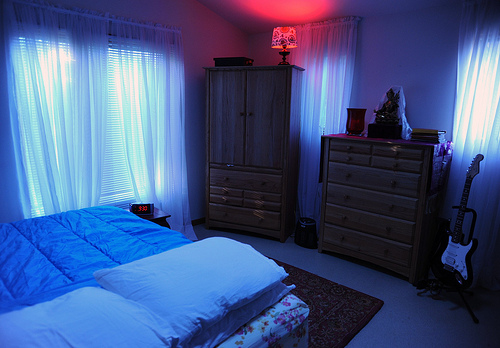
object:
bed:
[0, 206, 313, 348]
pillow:
[0, 237, 289, 348]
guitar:
[432, 153, 485, 289]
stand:
[431, 206, 480, 291]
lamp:
[271, 26, 298, 65]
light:
[240, 0, 329, 21]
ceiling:
[199, 0, 463, 35]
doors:
[211, 70, 286, 169]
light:
[8, 34, 499, 220]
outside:
[9, 34, 499, 220]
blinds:
[0, 0, 500, 292]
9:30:
[135, 206, 147, 212]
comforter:
[0, 205, 311, 348]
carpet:
[265, 255, 385, 348]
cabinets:
[317, 133, 453, 288]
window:
[7, 37, 165, 220]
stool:
[125, 207, 172, 229]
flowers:
[217, 292, 311, 348]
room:
[0, 0, 500, 348]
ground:
[192, 225, 500, 348]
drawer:
[326, 182, 418, 221]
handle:
[343, 194, 348, 200]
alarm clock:
[129, 202, 155, 218]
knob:
[247, 112, 250, 116]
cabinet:
[202, 64, 305, 243]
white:
[441, 236, 473, 280]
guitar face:
[431, 217, 479, 289]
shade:
[271, 26, 298, 49]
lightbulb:
[282, 45, 287, 48]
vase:
[346, 108, 367, 137]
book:
[412, 128, 447, 134]